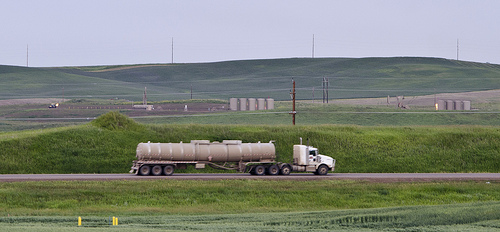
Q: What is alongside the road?
A: Grass.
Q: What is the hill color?
A: Green.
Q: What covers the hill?
A: Grass.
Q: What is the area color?
A: Green.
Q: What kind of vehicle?
A: Tractor trailer.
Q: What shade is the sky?
A: Light blue.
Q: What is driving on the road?
A: An 18 Wheeler.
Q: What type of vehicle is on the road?
A: An 18 wheeler.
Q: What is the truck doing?
A: Driving on the road.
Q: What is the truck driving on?
A: The road.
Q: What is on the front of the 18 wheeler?
A: A cab.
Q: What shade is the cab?
A: White.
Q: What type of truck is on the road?
A: An 18 wheeler.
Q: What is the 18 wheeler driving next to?
A: The grass.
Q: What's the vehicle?
A: Large truck.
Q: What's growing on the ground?
A: Grass.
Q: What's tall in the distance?
A: Mountains.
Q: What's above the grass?
A: Sky.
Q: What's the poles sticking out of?
A: Mountains.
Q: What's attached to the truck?
A: Long tank.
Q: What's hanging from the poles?
A: Wires.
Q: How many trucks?
A: One.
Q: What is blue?
A: Sky.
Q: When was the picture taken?
A: Daytime.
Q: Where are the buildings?
A: Behind the truck.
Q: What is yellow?
A: Markers.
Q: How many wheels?
A: Eighteen.